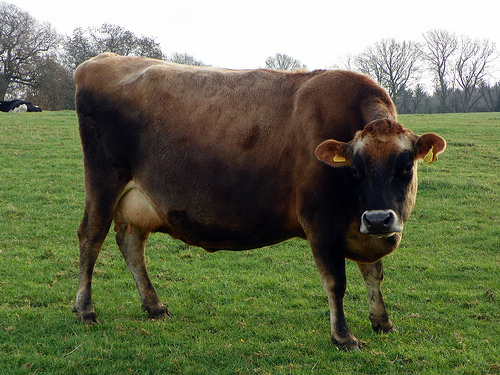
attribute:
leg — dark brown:
[359, 260, 394, 331]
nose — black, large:
[363, 210, 394, 235]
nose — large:
[359, 209, 402, 229]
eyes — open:
[353, 165, 413, 175]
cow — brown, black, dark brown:
[72, 48, 446, 348]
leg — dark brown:
[73, 162, 134, 320]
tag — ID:
[418, 145, 437, 164]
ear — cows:
[415, 129, 448, 169]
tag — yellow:
[418, 139, 437, 171]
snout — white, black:
[355, 205, 400, 234]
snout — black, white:
[357, 205, 406, 243]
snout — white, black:
[357, 205, 404, 235]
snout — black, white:
[361, 205, 402, 239]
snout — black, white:
[357, 209, 398, 232]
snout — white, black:
[353, 204, 415, 229]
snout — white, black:
[347, 206, 398, 246]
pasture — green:
[3, 104, 454, 365]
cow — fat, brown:
[37, 43, 443, 333]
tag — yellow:
[419, 148, 439, 167]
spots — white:
[345, 126, 408, 161]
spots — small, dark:
[149, 101, 285, 180]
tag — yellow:
[426, 133, 438, 170]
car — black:
[0, 93, 50, 126]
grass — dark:
[412, 175, 495, 339]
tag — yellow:
[315, 150, 364, 169]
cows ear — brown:
[296, 113, 362, 190]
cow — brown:
[0, 51, 473, 261]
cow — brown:
[68, 33, 494, 356]